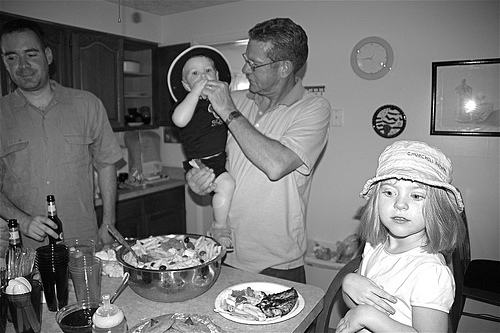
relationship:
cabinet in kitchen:
[71, 28, 191, 127] [0, 24, 477, 318]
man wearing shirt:
[0, 26, 123, 259] [230, 90, 332, 244]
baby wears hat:
[171, 56, 235, 252] [166, 46, 234, 102]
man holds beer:
[0, 26, 123, 259] [42, 194, 68, 250]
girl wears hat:
[338, 180, 467, 332] [362, 139, 467, 223]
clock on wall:
[350, 35, 394, 79] [170, 4, 497, 281]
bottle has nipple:
[86, 293, 132, 332] [93, 294, 115, 316]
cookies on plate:
[147, 316, 202, 332] [134, 310, 217, 332]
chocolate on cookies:
[148, 318, 195, 326] [147, 316, 202, 332]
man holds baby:
[186, 17, 330, 281] [171, 56, 235, 252]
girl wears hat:
[338, 180, 467, 332] [166, 46, 234, 102]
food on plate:
[223, 287, 297, 322] [211, 278, 310, 328]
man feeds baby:
[186, 17, 330, 281] [171, 56, 235, 252]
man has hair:
[0, 26, 123, 259] [1, 19, 43, 44]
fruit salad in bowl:
[125, 236, 217, 269] [114, 233, 226, 303]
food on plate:
[223, 287, 297, 322] [134, 310, 217, 332]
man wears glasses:
[186, 17, 330, 281] [242, 53, 290, 75]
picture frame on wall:
[428, 60, 499, 138] [170, 4, 497, 281]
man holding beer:
[0, 26, 123, 259] [42, 194, 68, 250]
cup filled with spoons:
[2, 291, 43, 331] [4, 278, 39, 332]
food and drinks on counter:
[7, 229, 293, 332] [104, 272, 325, 332]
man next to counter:
[0, 26, 123, 259] [104, 272, 325, 332]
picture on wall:
[370, 103, 407, 139] [170, 4, 497, 281]